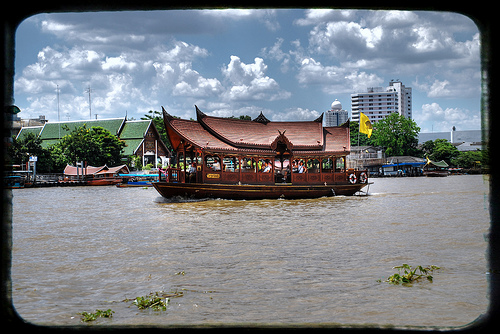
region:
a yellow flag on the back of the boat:
[354, 106, 374, 187]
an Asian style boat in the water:
[135, 92, 378, 232]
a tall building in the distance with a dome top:
[313, 88, 353, 132]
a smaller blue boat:
[110, 165, 167, 194]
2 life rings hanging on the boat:
[341, 163, 369, 193]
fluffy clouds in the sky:
[138, 17, 343, 102]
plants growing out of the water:
[380, 250, 449, 294]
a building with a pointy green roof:
[18, 106, 166, 188]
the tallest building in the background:
[347, 66, 429, 182]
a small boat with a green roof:
[420, 153, 454, 184]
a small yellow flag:
[354, 107, 376, 139]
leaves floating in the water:
[376, 260, 443, 292]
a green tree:
[48, 117, 127, 169]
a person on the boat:
[208, 156, 223, 172]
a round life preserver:
[345, 170, 361, 185]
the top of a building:
[328, 95, 341, 109]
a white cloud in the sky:
[213, 52, 294, 108]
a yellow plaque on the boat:
[203, 171, 223, 181]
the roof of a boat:
[157, 100, 354, 159]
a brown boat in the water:
[144, 94, 380, 201]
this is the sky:
[131, 12, 237, 51]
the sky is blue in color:
[213, 31, 264, 46]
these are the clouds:
[153, 55, 203, 101]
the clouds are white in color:
[166, 66, 188, 79]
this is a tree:
[64, 127, 109, 155]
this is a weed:
[389, 265, 434, 280]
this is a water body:
[178, 215, 366, 271]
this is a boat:
[157, 177, 369, 194]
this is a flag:
[358, 112, 370, 136]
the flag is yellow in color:
[360, 119, 365, 133]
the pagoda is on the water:
[121, 94, 448, 249]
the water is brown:
[123, 206, 397, 293]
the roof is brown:
[151, 101, 388, 192]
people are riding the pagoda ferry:
[146, 118, 391, 208]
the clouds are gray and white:
[114, 49, 269, 111]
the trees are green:
[43, 125, 118, 163]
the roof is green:
[39, 97, 200, 191]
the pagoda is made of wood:
[136, 129, 376, 197]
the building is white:
[323, 67, 445, 149]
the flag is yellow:
[345, 107, 397, 149]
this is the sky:
[138, 14, 298, 93]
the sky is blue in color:
[210, 27, 248, 44]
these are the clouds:
[323, 21, 424, 72]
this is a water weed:
[393, 264, 431, 282]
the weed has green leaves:
[391, 272, 401, 279]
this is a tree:
[68, 126, 118, 158]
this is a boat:
[157, 178, 363, 198]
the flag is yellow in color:
[360, 124, 365, 128]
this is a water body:
[197, 208, 324, 273]